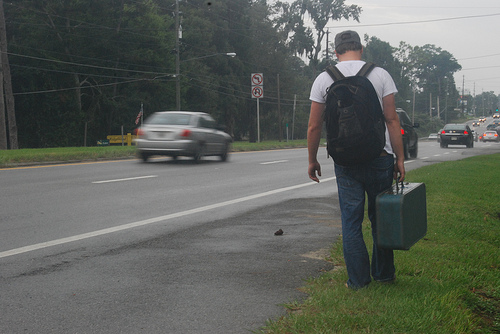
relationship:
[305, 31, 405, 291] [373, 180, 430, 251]
man holding suitcase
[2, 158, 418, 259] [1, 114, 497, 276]
line on road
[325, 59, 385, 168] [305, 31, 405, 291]
backpack on man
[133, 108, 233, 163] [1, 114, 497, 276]
car on road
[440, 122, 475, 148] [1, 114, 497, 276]
car on road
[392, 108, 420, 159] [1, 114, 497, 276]
car on road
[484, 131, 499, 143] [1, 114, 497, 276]
car on road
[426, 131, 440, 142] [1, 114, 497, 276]
car on road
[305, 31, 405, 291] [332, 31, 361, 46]
man wearing baseball cap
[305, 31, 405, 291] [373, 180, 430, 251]
man carrying suitcase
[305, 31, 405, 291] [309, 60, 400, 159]
man wearing shirt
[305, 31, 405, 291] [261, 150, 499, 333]
man standing in grass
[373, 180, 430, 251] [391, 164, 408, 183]
suitcase in hand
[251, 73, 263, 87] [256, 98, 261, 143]
sign on pole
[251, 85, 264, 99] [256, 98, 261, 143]
sign on pole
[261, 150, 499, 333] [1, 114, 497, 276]
grass on side of road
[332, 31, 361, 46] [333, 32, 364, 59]
baseball cap on head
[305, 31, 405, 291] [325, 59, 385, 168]
man wearing backpack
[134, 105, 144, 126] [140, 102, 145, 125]
flag on pole